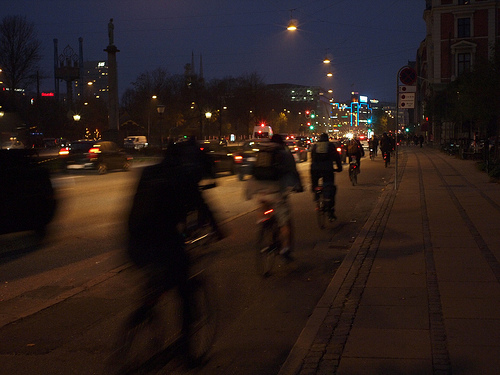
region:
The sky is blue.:
[216, 10, 255, 52]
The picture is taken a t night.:
[2, 0, 498, 372]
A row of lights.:
[274, 18, 345, 108]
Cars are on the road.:
[2, 119, 132, 280]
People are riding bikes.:
[108, 117, 409, 369]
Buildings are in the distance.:
[248, 67, 430, 148]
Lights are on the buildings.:
[278, 77, 424, 154]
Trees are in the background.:
[118, 51, 273, 123]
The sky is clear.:
[126, 7, 261, 42]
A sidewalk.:
[291, 141, 498, 372]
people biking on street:
[224, 127, 458, 348]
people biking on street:
[231, 102, 389, 286]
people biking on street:
[107, 44, 354, 305]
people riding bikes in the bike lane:
[150, 112, 417, 335]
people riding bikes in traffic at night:
[228, 17, 385, 191]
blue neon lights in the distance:
[311, 89, 383, 141]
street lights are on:
[273, 11, 345, 116]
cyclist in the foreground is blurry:
[116, 129, 258, 359]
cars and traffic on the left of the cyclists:
[51, 115, 311, 166]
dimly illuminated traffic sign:
[387, 62, 429, 127]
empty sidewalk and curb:
[349, 167, 482, 334]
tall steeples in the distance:
[26, 12, 270, 111]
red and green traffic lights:
[293, 102, 350, 132]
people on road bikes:
[238, 60, 430, 351]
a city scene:
[8, 10, 488, 360]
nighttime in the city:
[18, 7, 476, 367]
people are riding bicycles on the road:
[118, 104, 420, 362]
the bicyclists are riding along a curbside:
[102, 100, 434, 372]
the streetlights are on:
[46, 17, 358, 149]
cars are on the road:
[3, 118, 410, 252]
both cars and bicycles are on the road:
[11, 112, 411, 364]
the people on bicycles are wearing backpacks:
[246, 128, 364, 270]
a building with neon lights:
[319, 85, 396, 147]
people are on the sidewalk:
[396, 122, 435, 154]